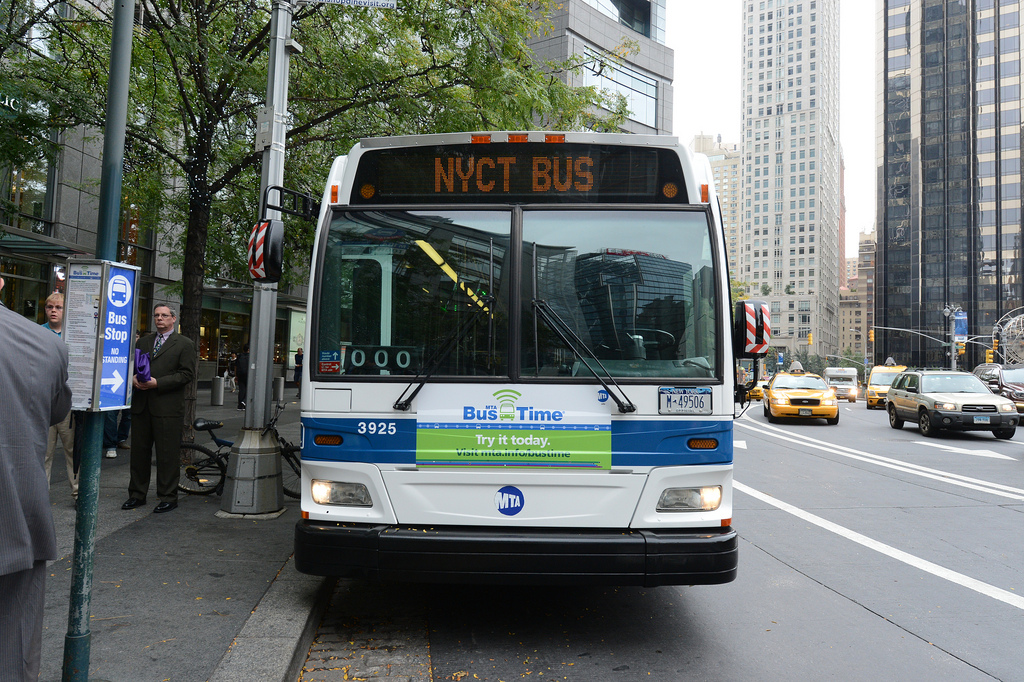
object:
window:
[756, 221, 769, 237]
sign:
[92, 258, 140, 414]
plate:
[654, 387, 719, 414]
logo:
[495, 482, 527, 516]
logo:
[462, 384, 561, 422]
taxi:
[764, 369, 840, 424]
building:
[734, 5, 847, 341]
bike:
[170, 412, 306, 505]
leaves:
[359, 11, 535, 120]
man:
[124, 298, 203, 517]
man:
[0, 267, 72, 682]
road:
[687, 488, 1021, 678]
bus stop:
[46, 259, 146, 675]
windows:
[757, 12, 767, 26]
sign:
[354, 144, 682, 204]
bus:
[289, 122, 745, 588]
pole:
[219, 259, 290, 517]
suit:
[128, 325, 200, 509]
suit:
[0, 303, 72, 679]